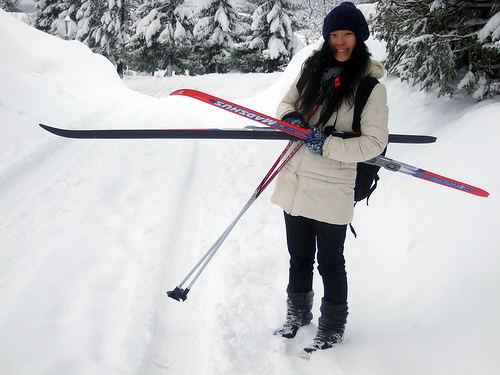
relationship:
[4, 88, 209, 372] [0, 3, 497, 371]
tracks in snow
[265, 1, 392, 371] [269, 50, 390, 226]
lady wearing jacket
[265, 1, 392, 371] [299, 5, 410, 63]
lady wearing cap